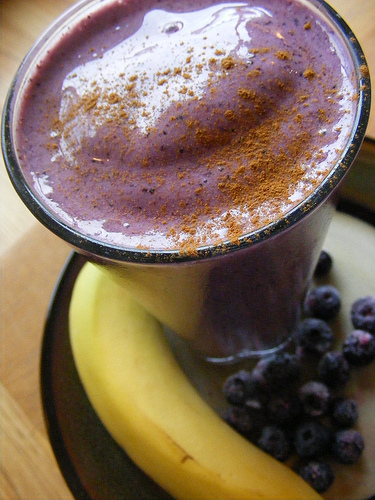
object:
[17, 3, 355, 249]
smoothy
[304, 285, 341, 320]
blueberry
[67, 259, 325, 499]
banana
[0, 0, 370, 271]
plate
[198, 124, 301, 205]
powder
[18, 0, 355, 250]
glass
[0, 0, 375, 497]
table